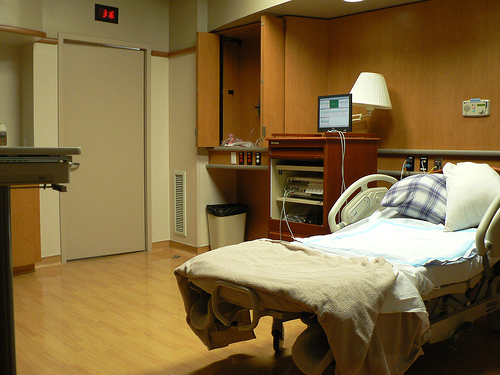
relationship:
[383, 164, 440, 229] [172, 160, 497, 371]
pillow on bed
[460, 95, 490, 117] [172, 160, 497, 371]
control box above bed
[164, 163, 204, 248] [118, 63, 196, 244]
vent on wall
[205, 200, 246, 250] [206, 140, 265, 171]
bag under shelf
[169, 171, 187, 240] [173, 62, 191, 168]
vent in wall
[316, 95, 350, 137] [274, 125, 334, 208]
monitor on top of dresser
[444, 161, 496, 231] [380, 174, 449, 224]
white pillow next to pillow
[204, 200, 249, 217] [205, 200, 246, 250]
bag in bag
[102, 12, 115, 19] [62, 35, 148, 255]
number over door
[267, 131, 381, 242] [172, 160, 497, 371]
dresser by bed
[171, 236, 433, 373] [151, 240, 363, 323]
blanket across foot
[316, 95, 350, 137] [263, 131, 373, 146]
monitor on shelf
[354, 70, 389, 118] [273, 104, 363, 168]
lamp on shelf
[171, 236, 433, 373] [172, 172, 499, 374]
blanket on bed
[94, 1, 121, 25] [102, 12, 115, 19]
clock in number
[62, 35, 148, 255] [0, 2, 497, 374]
door in room